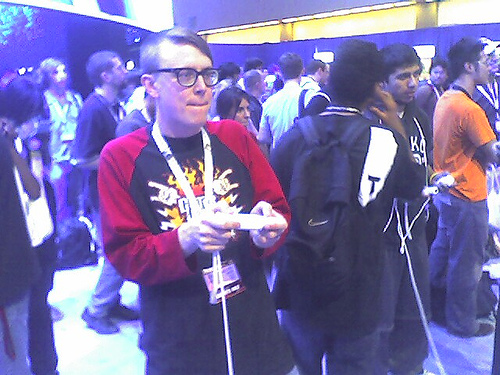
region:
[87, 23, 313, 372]
he is playing a video game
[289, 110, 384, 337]
this is a black backpack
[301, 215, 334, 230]
the Nike swoosh logo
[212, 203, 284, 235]
a Nintendo Wii controller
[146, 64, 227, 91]
a pair of eye glasses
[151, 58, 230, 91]
black rimmed glasses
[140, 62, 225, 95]
the frame of the glasses is black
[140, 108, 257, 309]
he is wearing a white lanyard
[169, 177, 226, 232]
this is the Guitar Hero logo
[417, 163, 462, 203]
the Nintendo Wii nunchuk controller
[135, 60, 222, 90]
Man wearing glasses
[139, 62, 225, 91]
Man is wearing glasses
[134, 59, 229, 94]
Man wearing black glasses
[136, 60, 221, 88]
Man is wearing black glasses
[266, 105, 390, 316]
Man wearing a backpack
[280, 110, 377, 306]
Man is wearing a backpack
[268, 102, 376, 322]
Man wearing a black backpack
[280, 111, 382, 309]
Man is wearing a black backpack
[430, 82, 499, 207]
Man wearing an orange t-shirt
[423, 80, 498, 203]
Man is wearing an orange t-shirt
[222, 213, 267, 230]
a Wii video game controller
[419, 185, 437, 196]
a Wii video game controller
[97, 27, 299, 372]
a young man playing video game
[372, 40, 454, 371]
a young man playing video game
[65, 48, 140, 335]
a man standing in room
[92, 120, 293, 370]
a red and black printed t-shirt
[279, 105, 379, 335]
a large black backpack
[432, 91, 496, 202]
a man's orange t-shirt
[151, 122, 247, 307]
a white lanyard with namebadge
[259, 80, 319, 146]
a man's white shirt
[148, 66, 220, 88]
a pair of men's eyeglasses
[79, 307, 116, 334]
a man's black shoe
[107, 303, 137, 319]
a man's black shoe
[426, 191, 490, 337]
a pair of grey pants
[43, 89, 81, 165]
a man's blue shirt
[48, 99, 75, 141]
a lanyard with name tag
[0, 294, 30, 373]
a pair of blue jeans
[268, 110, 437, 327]
a black and white shirt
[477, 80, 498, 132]
a white lanyard with name tag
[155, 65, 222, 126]
A face is wearing glasses.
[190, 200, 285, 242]
two hands are holding a controller.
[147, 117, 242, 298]
A tag is hanging on a neck.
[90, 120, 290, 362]
A shirt is red and black with logos.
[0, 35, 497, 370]
a crowd is in a room.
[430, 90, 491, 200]
A shirt is yellow.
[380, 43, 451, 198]
a man is holding two remotes.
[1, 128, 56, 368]
the clothes are mostly blue.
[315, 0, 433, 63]
two wall lights are shining.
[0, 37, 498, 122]
men and women are standing around